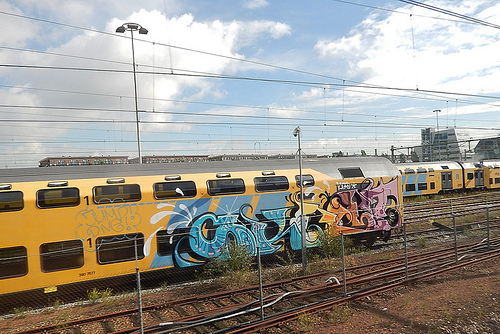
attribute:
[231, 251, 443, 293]
tracks — section, brown, train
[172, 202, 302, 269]
graffiti — blue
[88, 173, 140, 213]
window — long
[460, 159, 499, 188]
passenger car — yellow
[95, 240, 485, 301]
fence — tall, clear, link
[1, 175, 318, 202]
windows — glass, clear, dark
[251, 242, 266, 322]
post — silver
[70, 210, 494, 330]
fence — clear, link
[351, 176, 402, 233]
graffiti — pink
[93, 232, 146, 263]
window — long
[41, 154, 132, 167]
apartment building — brown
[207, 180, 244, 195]
window — long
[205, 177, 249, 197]
window — long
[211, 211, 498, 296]
fence — chain link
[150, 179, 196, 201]
window — long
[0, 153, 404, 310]
train — yellow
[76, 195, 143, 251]
graffiti — gray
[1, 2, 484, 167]
sky — blue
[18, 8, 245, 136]
cloud — white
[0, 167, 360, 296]
paint — yellow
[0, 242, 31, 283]
window — long